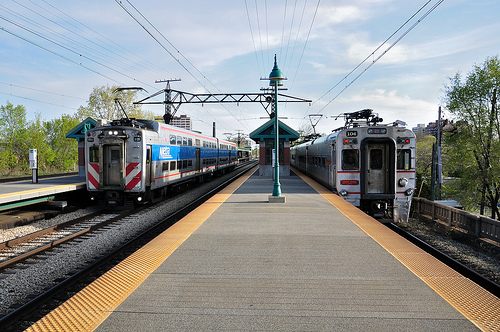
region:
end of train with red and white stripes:
[74, 118, 151, 205]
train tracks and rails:
[7, 200, 110, 292]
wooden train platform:
[126, 199, 426, 330]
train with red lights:
[333, 118, 417, 214]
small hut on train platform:
[241, 115, 307, 182]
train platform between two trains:
[52, 104, 432, 221]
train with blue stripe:
[75, 108, 247, 195]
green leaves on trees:
[0, 93, 79, 173]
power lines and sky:
[6, 4, 471, 83]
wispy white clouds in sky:
[16, 6, 484, 82]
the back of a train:
[330, 124, 422, 216]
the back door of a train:
[359, 118, 393, 203]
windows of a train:
[333, 127, 416, 172]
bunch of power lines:
[219, 3, 429, 67]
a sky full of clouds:
[72, 20, 282, 67]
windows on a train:
[148, 145, 199, 172]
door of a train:
[102, 135, 129, 184]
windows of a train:
[85, 143, 129, 164]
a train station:
[251, 120, 301, 174]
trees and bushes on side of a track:
[438, 71, 498, 212]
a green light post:
[265, 53, 285, 198]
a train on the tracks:
[84, 116, 242, 198]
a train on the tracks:
[288, 118, 416, 221]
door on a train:
[361, 139, 386, 199]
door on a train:
[99, 140, 123, 187]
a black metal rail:
[133, 89, 310, 104]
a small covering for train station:
[250, 116, 297, 173]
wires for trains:
[0, 0, 488, 125]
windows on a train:
[159, 158, 192, 171]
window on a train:
[342, 146, 359, 171]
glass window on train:
[90, 145, 99, 162]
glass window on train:
[145, 148, 152, 162]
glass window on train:
[161, 161, 168, 173]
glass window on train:
[169, 161, 176, 172]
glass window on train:
[176, 160, 183, 169]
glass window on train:
[185, 159, 192, 170]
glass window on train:
[169, 135, 178, 145]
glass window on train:
[176, 136, 183, 145]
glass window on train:
[187, 137, 193, 147]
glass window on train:
[340, 149, 356, 169]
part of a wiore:
[271, 30, 298, 82]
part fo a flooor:
[266, 265, 296, 310]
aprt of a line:
[191, 219, 201, 241]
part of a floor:
[284, 231, 315, 284]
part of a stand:
[271, 145, 314, 200]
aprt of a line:
[168, 211, 200, 266]